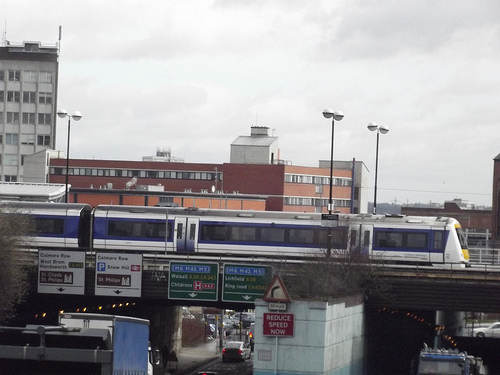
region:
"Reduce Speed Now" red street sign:
[261, 311, 293, 337]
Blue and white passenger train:
[0, 200, 473, 267]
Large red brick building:
[47, 157, 352, 213]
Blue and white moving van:
[56, 310, 158, 371]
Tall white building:
[0, 35, 60, 183]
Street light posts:
[321, 105, 387, 215]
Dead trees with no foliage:
[286, 242, 386, 298]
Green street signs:
[165, 256, 272, 302]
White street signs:
[32, 241, 142, 296]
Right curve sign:
[261, 273, 291, 303]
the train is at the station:
[5, 183, 471, 270]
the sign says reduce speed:
[253, 300, 298, 350]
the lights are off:
[286, 95, 344, 210]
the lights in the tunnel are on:
[375, 303, 470, 344]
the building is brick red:
[122, 160, 305, 203]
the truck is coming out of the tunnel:
[380, 327, 488, 372]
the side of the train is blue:
[85, 211, 458, 246]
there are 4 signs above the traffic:
[2, 238, 289, 310]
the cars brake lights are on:
[202, 332, 245, 359]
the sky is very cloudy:
[132, 19, 437, 178]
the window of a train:
[404, 229, 431, 251]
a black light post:
[324, 116, 336, 208]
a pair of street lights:
[321, 105, 347, 122]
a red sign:
[260, 307, 299, 340]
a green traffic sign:
[165, 258, 222, 308]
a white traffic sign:
[91, 247, 148, 301]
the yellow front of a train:
[454, 219, 471, 266]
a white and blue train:
[0, 197, 475, 259]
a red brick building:
[46, 154, 356, 216]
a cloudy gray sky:
[0, 0, 499, 210]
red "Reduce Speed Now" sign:
[264, 312, 294, 338]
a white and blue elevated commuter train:
[0, 203, 477, 276]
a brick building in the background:
[51, 151, 357, 218]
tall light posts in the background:
[322, 106, 393, 213]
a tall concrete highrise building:
[1, 62, 58, 181]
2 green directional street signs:
[167, 260, 273, 305]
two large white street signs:
[36, 247, 140, 297]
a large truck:
[416, 340, 485, 372]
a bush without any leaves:
[290, 217, 386, 304]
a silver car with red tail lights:
[218, 340, 251, 360]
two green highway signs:
[130, 219, 300, 323]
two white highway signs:
[12, 218, 182, 315]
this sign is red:
[252, 301, 337, 363]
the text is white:
[248, 303, 339, 358]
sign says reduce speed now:
[261, 305, 336, 357]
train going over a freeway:
[98, 172, 487, 349]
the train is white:
[240, 186, 492, 301]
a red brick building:
[216, 161, 324, 238]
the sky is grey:
[401, 157, 445, 184]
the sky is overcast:
[422, 163, 498, 191]